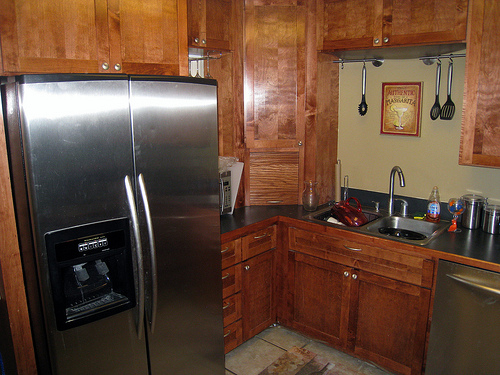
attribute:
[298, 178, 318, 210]
glass vase — clear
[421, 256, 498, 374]
dishwasher — silver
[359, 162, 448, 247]
sink — silver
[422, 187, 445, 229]
container — clear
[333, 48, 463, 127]
utensils — hanging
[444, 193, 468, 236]
glass — blue, orange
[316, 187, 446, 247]
sink — full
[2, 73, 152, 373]
door panel — recessed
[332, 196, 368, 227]
jug — red, glass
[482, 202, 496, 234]
canister — metal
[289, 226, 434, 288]
drawer — wooden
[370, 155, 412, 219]
sink fixtures — silver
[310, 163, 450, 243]
sink — large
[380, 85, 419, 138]
sign — brown, red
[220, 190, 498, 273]
counter top — solid, black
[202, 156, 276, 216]
microwave — silver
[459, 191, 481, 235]
canister — silver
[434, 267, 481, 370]
dish washer — silver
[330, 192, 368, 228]
pitcher — red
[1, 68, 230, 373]
appliance — large, metal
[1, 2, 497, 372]
kitchen — wood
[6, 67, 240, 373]
refrigerator — stainless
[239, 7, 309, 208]
cabinet — long, short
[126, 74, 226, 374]
door — double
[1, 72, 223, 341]
refrigerator — silver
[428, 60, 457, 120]
spatula — black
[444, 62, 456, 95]
handle — silver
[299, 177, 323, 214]
vase — glass, clear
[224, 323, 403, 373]
tiles — gray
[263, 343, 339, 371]
rug — printed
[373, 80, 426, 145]
picture — red and brown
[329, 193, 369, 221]
border — red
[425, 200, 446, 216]
label — blue